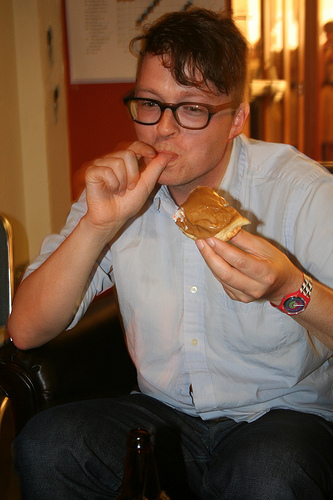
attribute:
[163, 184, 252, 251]
doughnut — half-eaten, caramel, brown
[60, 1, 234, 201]
wall — red, orange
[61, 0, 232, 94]
board — white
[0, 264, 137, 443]
chair — black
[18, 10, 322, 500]
man — eating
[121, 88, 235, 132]
glasses — brown, a pair, dark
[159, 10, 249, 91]
hair — brown, messy, black, shaved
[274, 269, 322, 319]
watch — red, black, multicolored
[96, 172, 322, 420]
shirt — baby blue, short sleeved, blue, light blue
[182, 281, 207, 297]
button — white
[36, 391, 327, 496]
pants — dark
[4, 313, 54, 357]
elbow — bent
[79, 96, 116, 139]
wall — red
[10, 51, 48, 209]
wall — beige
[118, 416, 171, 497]
bottle — brown, glass, reddish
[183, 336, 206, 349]
button — pearl finish